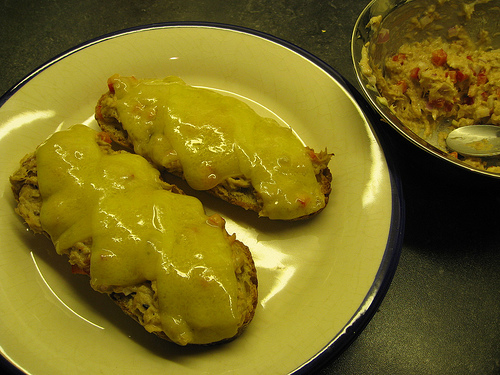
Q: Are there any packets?
A: No, there are no packets.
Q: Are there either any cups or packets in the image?
A: No, there are no packets or cups.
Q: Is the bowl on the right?
A: Yes, the bowl is on the right of the image.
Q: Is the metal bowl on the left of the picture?
A: No, the bowl is on the right of the image.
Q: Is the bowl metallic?
A: Yes, the bowl is metallic.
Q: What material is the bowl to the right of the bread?
A: The bowl is made of metal.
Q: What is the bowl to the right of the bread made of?
A: The bowl is made of metal.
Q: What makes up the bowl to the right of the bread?
A: The bowl is made of metal.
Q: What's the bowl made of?
A: The bowl is made of metal.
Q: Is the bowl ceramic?
A: No, the bowl is metallic.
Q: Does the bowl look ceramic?
A: No, the bowl is metallic.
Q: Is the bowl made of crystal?
A: No, the bowl is made of metal.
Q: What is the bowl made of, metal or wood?
A: The bowl is made of metal.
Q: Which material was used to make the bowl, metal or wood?
A: The bowl is made of metal.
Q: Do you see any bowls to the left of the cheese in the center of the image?
A: No, the bowl is to the right of the cheese.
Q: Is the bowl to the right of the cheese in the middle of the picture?
A: Yes, the bowl is to the right of the cheese.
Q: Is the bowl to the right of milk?
A: No, the bowl is to the right of the cheese.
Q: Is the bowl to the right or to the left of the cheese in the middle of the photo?
A: The bowl is to the right of the cheese.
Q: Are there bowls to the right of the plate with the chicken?
A: Yes, there is a bowl to the right of the plate.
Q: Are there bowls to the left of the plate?
A: No, the bowl is to the right of the plate.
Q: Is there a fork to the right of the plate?
A: No, there is a bowl to the right of the plate.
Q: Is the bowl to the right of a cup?
A: No, the bowl is to the right of the plate.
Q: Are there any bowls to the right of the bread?
A: Yes, there is a bowl to the right of the bread.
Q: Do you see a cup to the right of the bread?
A: No, there is a bowl to the right of the bread.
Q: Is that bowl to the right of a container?
A: No, the bowl is to the right of the bread.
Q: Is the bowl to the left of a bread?
A: No, the bowl is to the right of a bread.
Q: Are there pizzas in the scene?
A: No, there are no pizzas.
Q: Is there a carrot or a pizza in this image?
A: No, there are no pizzas or carrots.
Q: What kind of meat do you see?
A: The meat is chicken.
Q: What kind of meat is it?
A: The meat is chicken.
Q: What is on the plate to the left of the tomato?
A: The chicken is on the plate.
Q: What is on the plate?
A: The chicken is on the plate.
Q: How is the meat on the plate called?
A: The meat is chicken.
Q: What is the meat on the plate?
A: The meat is chicken.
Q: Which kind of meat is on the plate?
A: The meat is chicken.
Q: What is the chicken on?
A: The chicken is on the plate.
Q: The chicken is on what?
A: The chicken is on the plate.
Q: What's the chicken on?
A: The chicken is on the plate.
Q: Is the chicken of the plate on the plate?
A: Yes, the chicken is on the plate.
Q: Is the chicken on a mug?
A: No, the chicken is on the plate.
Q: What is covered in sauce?
A: The chicken is covered in sauce.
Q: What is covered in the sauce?
A: The chicken is covered in sauce.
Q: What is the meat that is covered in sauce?
A: The meat is chicken.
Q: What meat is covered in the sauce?
A: The meat is chicken.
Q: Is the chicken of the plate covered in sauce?
A: Yes, the chicken is covered in sauce.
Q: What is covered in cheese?
A: The chicken is covered in cheese.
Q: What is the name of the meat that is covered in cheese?
A: The meat is chicken.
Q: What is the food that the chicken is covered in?
A: The food is cheese.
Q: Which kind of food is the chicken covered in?
A: The chicken is covered in cheese.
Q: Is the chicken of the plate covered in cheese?
A: Yes, the chicken is covered in cheese.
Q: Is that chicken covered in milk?
A: No, the chicken is covered in cheese.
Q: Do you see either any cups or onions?
A: No, there are no cups or onions.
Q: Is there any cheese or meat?
A: Yes, there is cheese.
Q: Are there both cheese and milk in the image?
A: No, there is cheese but no milk.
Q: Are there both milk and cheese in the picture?
A: No, there is cheese but no milk.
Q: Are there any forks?
A: No, there are no forks.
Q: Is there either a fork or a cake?
A: No, there are no forks or cakes.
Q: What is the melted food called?
A: The food is cheese.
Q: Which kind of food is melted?
A: The food is cheese.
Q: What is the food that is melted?
A: The food is cheese.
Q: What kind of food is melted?
A: The food is cheese.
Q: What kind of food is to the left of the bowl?
A: The food is cheese.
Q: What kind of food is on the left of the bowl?
A: The food is cheese.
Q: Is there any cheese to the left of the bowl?
A: Yes, there is cheese to the left of the bowl.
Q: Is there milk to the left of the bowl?
A: No, there is cheese to the left of the bowl.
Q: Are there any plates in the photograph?
A: Yes, there is a plate.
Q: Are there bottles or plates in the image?
A: Yes, there is a plate.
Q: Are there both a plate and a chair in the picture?
A: No, there is a plate but no chairs.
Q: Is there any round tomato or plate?
A: Yes, there is a round plate.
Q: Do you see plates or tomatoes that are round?
A: Yes, the plate is round.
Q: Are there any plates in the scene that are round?
A: Yes, there is a round plate.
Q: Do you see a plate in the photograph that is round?
A: Yes, there is a plate that is round.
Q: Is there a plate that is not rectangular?
A: Yes, there is a round plate.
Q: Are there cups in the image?
A: No, there are no cups.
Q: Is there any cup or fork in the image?
A: No, there are no cups or forks.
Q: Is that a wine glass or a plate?
A: That is a plate.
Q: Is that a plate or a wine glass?
A: That is a plate.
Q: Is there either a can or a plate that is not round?
A: No, there is a plate but it is round.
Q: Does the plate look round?
A: Yes, the plate is round.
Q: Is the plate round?
A: Yes, the plate is round.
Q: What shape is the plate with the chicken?
A: The plate is round.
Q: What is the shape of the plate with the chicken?
A: The plate is round.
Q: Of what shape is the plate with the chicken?
A: The plate is round.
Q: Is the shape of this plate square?
A: No, the plate is round.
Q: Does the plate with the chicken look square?
A: No, the plate is round.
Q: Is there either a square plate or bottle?
A: No, there is a plate but it is round.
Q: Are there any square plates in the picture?
A: No, there is a plate but it is round.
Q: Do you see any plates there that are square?
A: No, there is a plate but it is round.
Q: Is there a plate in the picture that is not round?
A: No, there is a plate but it is round.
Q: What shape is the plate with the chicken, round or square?
A: The plate is round.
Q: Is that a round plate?
A: Yes, that is a round plate.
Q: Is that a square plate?
A: No, that is a round plate.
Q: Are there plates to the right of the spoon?
A: No, the plate is to the left of the spoon.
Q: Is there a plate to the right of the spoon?
A: No, the plate is to the left of the spoon.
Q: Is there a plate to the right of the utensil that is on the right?
A: No, the plate is to the left of the spoon.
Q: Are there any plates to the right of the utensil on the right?
A: No, the plate is to the left of the spoon.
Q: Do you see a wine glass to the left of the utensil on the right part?
A: No, there is a plate to the left of the spoon.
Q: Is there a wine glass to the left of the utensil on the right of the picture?
A: No, there is a plate to the left of the spoon.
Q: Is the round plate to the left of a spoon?
A: Yes, the plate is to the left of a spoon.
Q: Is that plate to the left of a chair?
A: No, the plate is to the left of a spoon.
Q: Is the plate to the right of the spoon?
A: No, the plate is to the left of the spoon.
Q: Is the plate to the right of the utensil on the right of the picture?
A: No, the plate is to the left of the spoon.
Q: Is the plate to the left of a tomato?
A: Yes, the plate is to the left of a tomato.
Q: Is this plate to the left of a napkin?
A: No, the plate is to the left of a tomato.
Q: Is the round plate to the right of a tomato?
A: No, the plate is to the left of a tomato.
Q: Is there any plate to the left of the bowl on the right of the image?
A: Yes, there is a plate to the left of the bowl.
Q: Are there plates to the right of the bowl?
A: No, the plate is to the left of the bowl.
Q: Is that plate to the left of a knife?
A: No, the plate is to the left of the bowl.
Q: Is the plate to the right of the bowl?
A: No, the plate is to the left of the bowl.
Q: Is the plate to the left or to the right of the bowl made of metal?
A: The plate is to the left of the bowl.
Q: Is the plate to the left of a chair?
A: No, the plate is to the left of a tomato.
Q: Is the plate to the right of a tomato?
A: No, the plate is to the left of a tomato.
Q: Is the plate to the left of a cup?
A: No, the plate is to the left of a tomato.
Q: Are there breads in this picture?
A: Yes, there is a bread.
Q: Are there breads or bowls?
A: Yes, there is a bread.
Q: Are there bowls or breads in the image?
A: Yes, there is a bread.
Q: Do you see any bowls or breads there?
A: Yes, there is a bread.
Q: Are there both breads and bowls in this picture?
A: Yes, there are both a bread and a bowl.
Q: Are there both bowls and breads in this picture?
A: Yes, there are both a bread and a bowl.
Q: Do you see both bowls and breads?
A: Yes, there are both a bread and a bowl.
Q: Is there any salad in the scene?
A: No, there is no salad.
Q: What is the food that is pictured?
A: The food is a bread.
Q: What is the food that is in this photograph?
A: The food is a bread.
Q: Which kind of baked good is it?
A: The food is a bread.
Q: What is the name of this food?
A: That is a bread.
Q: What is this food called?
A: That is a bread.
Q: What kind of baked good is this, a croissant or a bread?
A: That is a bread.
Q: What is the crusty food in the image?
A: The food is a bread.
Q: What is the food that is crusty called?
A: The food is a bread.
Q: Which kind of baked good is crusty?
A: The baked good is a bread.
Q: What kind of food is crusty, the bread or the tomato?
A: The bread is crusty.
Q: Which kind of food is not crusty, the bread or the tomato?
A: The tomato is not crusty.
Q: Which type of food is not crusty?
A: The food is a tomato.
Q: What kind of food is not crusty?
A: The food is a tomato.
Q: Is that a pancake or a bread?
A: That is a bread.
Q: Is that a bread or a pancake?
A: That is a bread.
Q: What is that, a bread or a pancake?
A: That is a bread.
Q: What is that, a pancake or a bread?
A: That is a bread.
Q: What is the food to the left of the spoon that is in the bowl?
A: The food is a bread.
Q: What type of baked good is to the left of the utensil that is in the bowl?
A: The food is a bread.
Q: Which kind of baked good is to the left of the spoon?
A: The food is a bread.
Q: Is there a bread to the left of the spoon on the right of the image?
A: Yes, there is a bread to the left of the spoon.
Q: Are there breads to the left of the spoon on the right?
A: Yes, there is a bread to the left of the spoon.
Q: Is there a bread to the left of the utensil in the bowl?
A: Yes, there is a bread to the left of the spoon.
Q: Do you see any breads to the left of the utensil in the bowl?
A: Yes, there is a bread to the left of the spoon.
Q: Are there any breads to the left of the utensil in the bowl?
A: Yes, there is a bread to the left of the spoon.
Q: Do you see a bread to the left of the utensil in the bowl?
A: Yes, there is a bread to the left of the spoon.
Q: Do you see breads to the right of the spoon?
A: No, the bread is to the left of the spoon.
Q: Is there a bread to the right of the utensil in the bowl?
A: No, the bread is to the left of the spoon.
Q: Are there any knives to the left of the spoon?
A: No, there is a bread to the left of the spoon.